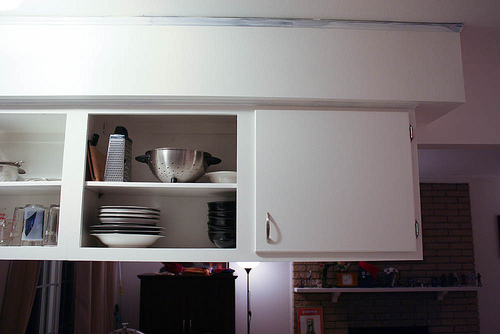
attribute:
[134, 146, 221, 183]
strainer — silver, black, present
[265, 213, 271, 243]
handle — silver, small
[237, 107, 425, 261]
cabinet — white, present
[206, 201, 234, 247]
bowls — shiny, present, stacked, black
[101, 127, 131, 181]
grater — silver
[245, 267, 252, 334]
stand — black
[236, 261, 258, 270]
lamp — on, tall, thin, white, black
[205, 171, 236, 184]
bowl — white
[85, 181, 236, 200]
shelf — white, elevated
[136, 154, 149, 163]
handle — black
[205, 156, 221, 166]
handle — black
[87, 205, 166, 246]
plates — stacked, present, white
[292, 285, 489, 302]
shelf — white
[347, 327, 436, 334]
fireplace — brick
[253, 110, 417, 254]
door — present, white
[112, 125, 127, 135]
handle — black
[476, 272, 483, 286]
figure — little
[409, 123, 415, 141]
hinge — silver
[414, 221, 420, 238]
hinge — silver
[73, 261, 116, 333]
curtain panel — tan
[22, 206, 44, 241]
design — blue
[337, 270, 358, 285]
clock — brown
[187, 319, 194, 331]
handle — silver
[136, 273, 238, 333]
cabinet — black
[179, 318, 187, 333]
handle — silver